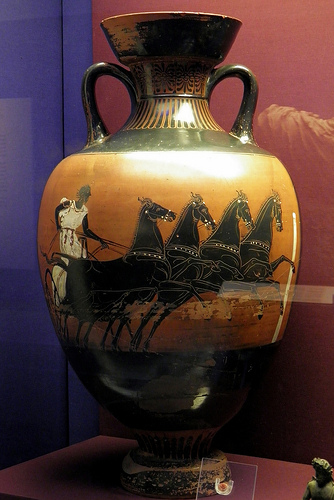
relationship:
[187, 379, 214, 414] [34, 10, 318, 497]
refection on urn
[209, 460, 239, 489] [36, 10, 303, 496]
area of pot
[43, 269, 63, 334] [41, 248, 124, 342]
wheel of a chariot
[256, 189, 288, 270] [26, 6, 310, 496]
horse on vase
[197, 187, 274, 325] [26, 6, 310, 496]
horse on vase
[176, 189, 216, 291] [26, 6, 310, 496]
horse on vase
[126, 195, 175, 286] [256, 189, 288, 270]
horse on horse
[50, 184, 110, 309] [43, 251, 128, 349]
driver in a chariot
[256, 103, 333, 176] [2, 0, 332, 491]
picture on wall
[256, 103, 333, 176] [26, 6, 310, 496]
picture behind vase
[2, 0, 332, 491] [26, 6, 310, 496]
wall behind vase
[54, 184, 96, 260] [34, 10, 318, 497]
driver on urn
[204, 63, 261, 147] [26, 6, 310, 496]
handle of a vase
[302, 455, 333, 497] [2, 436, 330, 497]
statue on table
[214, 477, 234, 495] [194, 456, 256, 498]
item in case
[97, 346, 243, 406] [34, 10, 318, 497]
patch on urn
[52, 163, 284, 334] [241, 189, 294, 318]
drawings of horse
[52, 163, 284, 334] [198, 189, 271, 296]
drawings of horse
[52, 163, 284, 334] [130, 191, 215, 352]
drawings of horse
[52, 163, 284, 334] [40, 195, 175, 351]
drawings of horse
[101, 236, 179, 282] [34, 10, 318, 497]
stripes on urn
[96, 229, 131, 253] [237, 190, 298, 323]
reins for horse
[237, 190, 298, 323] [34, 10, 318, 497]
horse on urn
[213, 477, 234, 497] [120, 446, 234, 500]
item on base